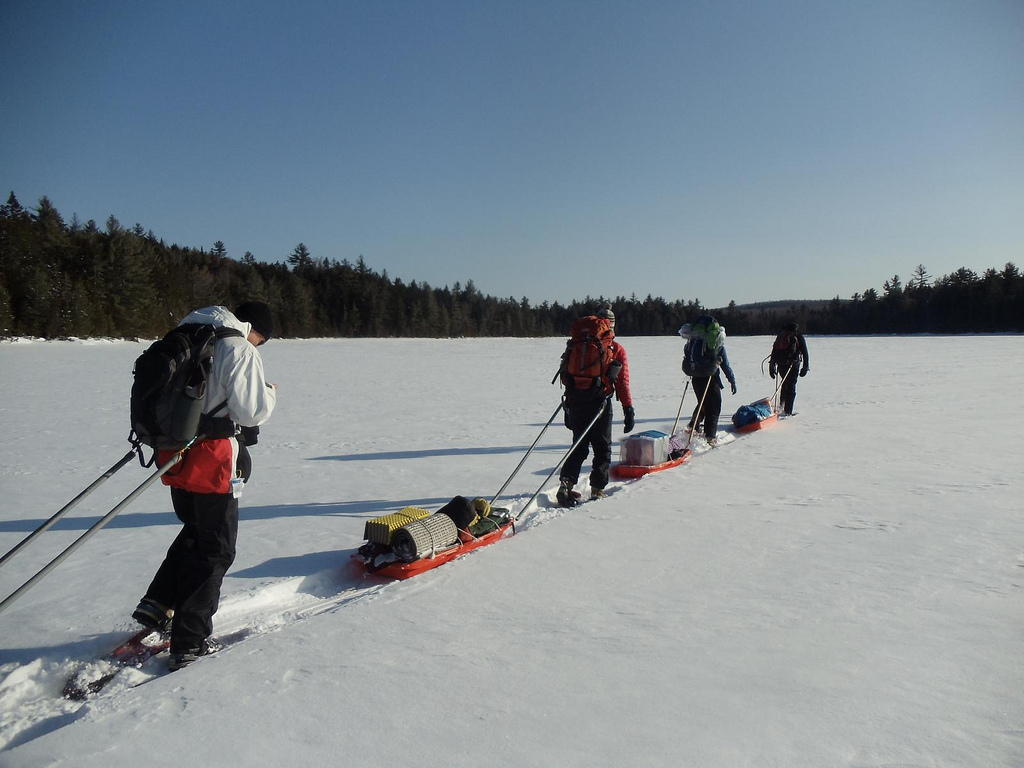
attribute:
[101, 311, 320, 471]
shirt — white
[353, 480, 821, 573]
cart — orange, pull, plastic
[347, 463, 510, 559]
package — yellow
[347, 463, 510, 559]
cart — orange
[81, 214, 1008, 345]
trees — green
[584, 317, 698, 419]
backpack — orange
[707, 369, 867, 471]
bag — blue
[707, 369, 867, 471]
surface — orange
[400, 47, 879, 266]
sky — blue, clear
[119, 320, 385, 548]
jacket — white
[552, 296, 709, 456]
jacket — orange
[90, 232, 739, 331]
trees — tall